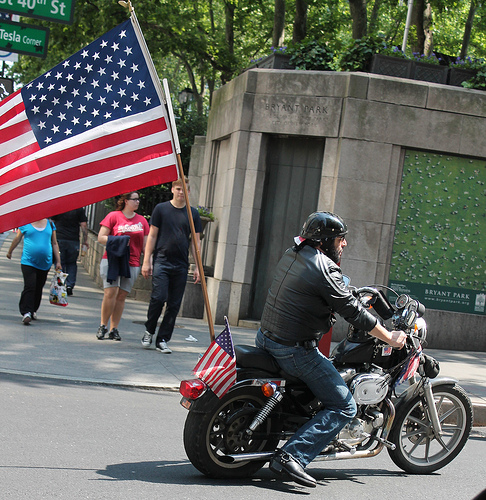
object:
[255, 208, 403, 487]
man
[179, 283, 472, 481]
motorcycle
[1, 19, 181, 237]
flag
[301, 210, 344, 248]
helmet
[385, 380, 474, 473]
wheel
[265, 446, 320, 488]
boot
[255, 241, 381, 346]
shirt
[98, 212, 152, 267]
shirt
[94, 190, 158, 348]
woman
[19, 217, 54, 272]
shirt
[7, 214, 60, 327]
person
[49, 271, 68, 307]
bag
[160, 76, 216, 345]
pole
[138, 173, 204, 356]
man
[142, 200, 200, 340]
black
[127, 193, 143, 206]
glasses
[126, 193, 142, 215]
face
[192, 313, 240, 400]
flag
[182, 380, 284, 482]
wheel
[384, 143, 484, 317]
picture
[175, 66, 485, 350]
wall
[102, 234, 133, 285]
jacket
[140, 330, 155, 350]
shoe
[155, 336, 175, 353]
shoe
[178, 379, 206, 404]
light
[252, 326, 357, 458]
jeans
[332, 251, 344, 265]
beard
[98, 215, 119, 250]
arm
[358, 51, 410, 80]
boxes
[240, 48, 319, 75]
boxes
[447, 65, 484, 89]
boxes